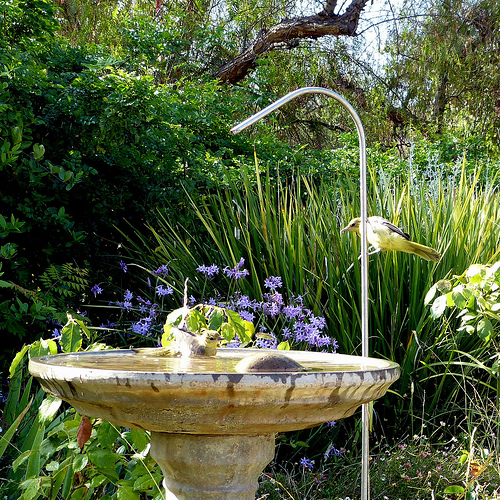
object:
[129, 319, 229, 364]
bird bath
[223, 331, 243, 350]
flower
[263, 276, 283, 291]
flower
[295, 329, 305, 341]
flower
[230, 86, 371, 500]
crook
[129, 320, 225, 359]
bird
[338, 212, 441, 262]
bird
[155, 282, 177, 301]
flower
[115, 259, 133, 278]
flower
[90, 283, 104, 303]
flower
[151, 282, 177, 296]
flower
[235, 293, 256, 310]
flower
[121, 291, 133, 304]
flower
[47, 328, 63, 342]
flower